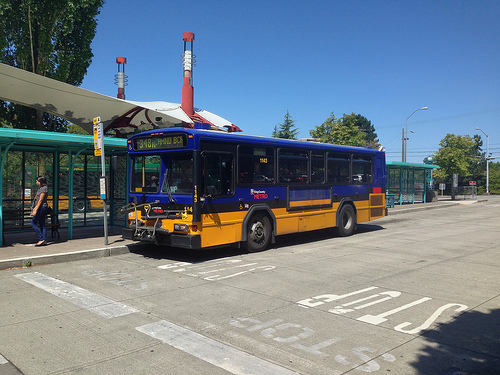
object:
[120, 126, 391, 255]
bus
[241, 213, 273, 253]
wheel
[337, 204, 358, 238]
wheel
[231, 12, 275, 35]
sky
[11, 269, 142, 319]
line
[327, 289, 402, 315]
letters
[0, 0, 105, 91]
tree